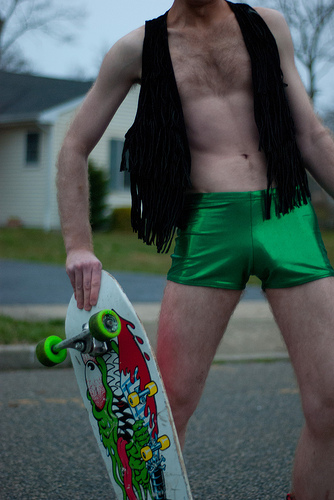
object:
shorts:
[161, 184, 332, 298]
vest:
[118, 3, 310, 249]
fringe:
[186, 174, 307, 205]